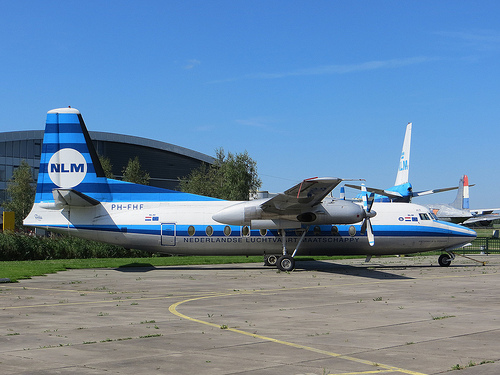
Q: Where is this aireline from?
A: Outside US.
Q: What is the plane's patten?
A: Stripe.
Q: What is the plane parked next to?
A: Airport.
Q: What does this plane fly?
A: Passengers.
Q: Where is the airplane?
A: On runway.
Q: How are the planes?
A: Parked.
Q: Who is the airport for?
A: Passengers.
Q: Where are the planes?
A: Tarmac.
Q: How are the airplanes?
A: Parked.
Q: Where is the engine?
A: On wing.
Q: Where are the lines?
A: On Tarmac.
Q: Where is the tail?
A: On airliner.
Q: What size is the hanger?
A: Large.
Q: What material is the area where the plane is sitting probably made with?
A: Asphalt.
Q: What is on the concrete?
A: An airplane.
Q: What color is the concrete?
A: Gray.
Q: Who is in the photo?
A: Nobody.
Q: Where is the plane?
A: On the concrete.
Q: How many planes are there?
A: Two.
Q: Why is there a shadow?
A: It is sunny.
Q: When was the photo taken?
A: Daytime.